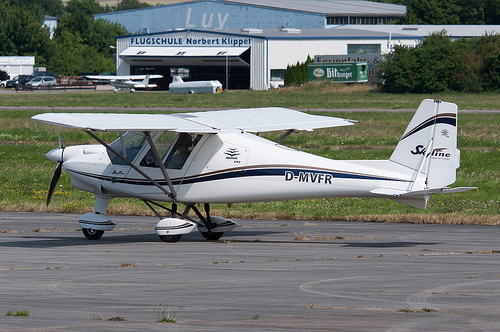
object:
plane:
[87, 72, 163, 94]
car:
[25, 74, 57, 91]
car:
[1, 74, 33, 91]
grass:
[99, 309, 188, 326]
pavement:
[5, 209, 494, 331]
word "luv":
[179, 3, 231, 31]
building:
[90, 0, 499, 40]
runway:
[1, 211, 498, 328]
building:
[113, 27, 425, 89]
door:
[119, 46, 249, 86]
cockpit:
[110, 128, 205, 177]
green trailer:
[307, 62, 367, 85]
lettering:
[322, 66, 354, 78]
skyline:
[405, 142, 449, 162]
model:
[30, 93, 482, 241]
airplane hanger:
[112, 28, 426, 91]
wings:
[25, 106, 357, 135]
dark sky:
[366, 28, 489, 100]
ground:
[0, 194, 499, 332]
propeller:
[43, 125, 68, 207]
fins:
[396, 89, 479, 209]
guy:
[169, 133, 194, 168]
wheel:
[158, 233, 182, 245]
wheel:
[199, 228, 225, 244]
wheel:
[80, 227, 103, 244]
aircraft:
[27, 97, 478, 241]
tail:
[374, 99, 457, 209]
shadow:
[0, 230, 447, 250]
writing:
[282, 170, 334, 186]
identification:
[276, 163, 336, 184]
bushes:
[372, 26, 500, 98]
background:
[1, 14, 498, 114]